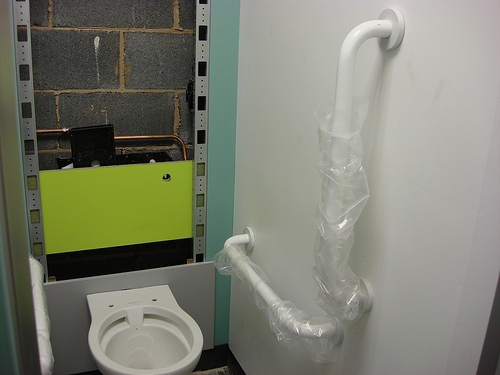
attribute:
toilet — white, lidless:
[85, 283, 205, 374]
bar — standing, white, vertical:
[322, 9, 402, 315]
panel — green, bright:
[39, 159, 194, 256]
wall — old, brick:
[32, 1, 196, 160]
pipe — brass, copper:
[36, 127, 69, 132]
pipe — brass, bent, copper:
[114, 133, 189, 159]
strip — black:
[198, 344, 227, 370]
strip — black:
[226, 345, 244, 374]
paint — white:
[91, 35, 104, 80]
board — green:
[207, 1, 237, 347]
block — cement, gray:
[14, 28, 121, 91]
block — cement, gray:
[121, 28, 204, 89]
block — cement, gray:
[59, 91, 178, 144]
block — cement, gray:
[51, 0, 175, 29]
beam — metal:
[10, 1, 48, 278]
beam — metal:
[196, 1, 211, 262]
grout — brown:
[21, 26, 198, 33]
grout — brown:
[36, 88, 198, 92]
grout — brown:
[117, 29, 128, 91]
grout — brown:
[174, 89, 179, 144]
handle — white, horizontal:
[224, 226, 341, 352]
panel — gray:
[32, 260, 217, 374]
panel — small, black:
[68, 123, 118, 166]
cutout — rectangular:
[15, 22, 30, 45]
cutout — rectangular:
[19, 63, 31, 81]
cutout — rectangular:
[21, 101, 34, 119]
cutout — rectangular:
[200, 24, 209, 42]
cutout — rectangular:
[198, 60, 207, 79]